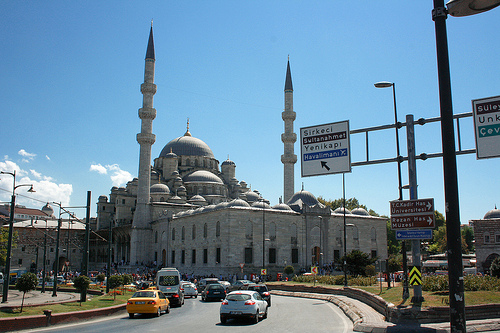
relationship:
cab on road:
[125, 287, 170, 321] [19, 292, 351, 331]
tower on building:
[134, 25, 160, 276] [93, 16, 389, 278]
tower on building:
[277, 54, 301, 211] [93, 16, 389, 278]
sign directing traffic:
[391, 197, 436, 214] [55, 267, 269, 324]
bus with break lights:
[155, 268, 187, 305] [158, 288, 181, 301]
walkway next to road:
[271, 255, 416, 330] [8, 271, 354, 327]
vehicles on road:
[2, 268, 275, 325] [8, 271, 354, 327]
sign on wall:
[299, 119, 353, 176] [297, 118, 350, 178]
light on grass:
[373, 78, 410, 293] [362, 279, 498, 314]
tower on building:
[126, 12, 161, 276] [74, 11, 391, 286]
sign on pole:
[389, 226, 434, 239] [405, 111, 429, 299]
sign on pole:
[408, 260, 424, 290] [401, 110, 426, 302]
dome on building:
[158, 132, 214, 157] [94, 131, 389, 273]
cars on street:
[124, 264, 277, 326] [0, 268, 355, 328]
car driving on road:
[198, 280, 227, 304] [35, 287, 355, 330]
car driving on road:
[240, 285, 272, 307] [4, 290, 355, 330]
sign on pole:
[408, 260, 424, 290] [401, 108, 431, 315]